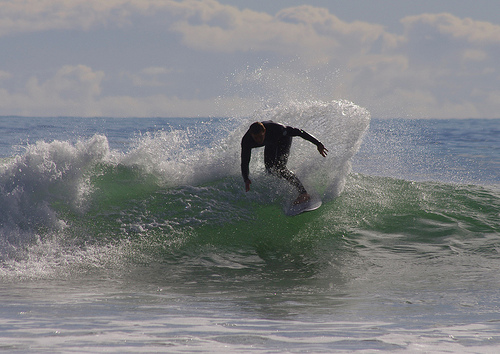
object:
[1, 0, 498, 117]
clouds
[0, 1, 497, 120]
sky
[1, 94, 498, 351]
water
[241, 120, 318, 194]
wetsuit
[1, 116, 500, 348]
sea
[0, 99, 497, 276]
splash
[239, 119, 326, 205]
man wetsuit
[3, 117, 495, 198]
surface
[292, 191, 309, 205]
foot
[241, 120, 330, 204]
man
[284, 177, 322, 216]
surfboard